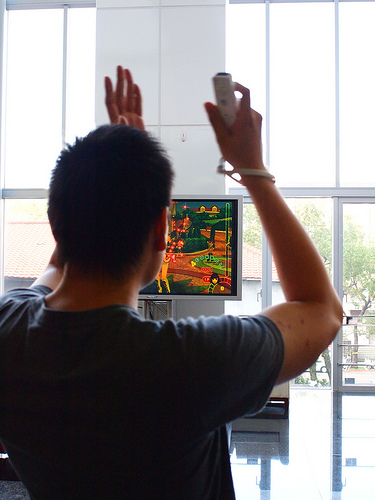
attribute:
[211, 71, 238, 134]
remote — white, wii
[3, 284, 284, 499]
shirt — gray, black, blue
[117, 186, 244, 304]
tv — flat screen, large, on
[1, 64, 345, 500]
person — playing wii, asian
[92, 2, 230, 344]
wall — white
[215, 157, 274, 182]
lanyard — cream, white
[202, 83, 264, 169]
hands — in air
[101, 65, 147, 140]
hands — pointing up, in air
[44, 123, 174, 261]
hair — black, spiky, short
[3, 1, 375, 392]
windows — shining, building, modern paned, large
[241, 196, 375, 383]
tree — green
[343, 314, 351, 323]
handle — silver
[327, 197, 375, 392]
door — metal, glass